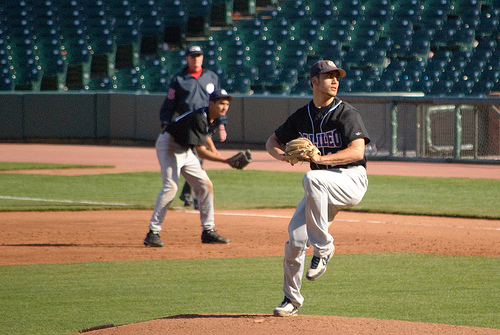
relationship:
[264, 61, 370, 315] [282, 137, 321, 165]
pitcher wearing cathcher's mitt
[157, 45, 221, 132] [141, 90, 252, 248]
base coach behind catcher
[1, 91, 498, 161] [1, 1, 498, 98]
wall in front of bleachers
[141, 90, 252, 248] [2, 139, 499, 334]
catcher standing on field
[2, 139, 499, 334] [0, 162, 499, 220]
field has grass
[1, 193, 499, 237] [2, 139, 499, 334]
line on field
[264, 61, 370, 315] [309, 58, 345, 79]
pitcher wearing cap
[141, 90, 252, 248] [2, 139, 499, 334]
catcher in field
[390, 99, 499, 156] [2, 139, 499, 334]
fence at side of field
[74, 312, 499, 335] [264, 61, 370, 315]
mound for pitcher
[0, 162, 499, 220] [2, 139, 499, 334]
grass on field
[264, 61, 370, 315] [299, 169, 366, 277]
pitcher has leg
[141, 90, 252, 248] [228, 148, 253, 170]
catcher wears glove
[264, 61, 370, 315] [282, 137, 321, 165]
pitcher wears cathcher's mitt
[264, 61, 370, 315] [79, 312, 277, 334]
pitcher has shadow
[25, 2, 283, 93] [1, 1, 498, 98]
stairs in bleachers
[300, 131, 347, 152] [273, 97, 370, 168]
galileo on shirt